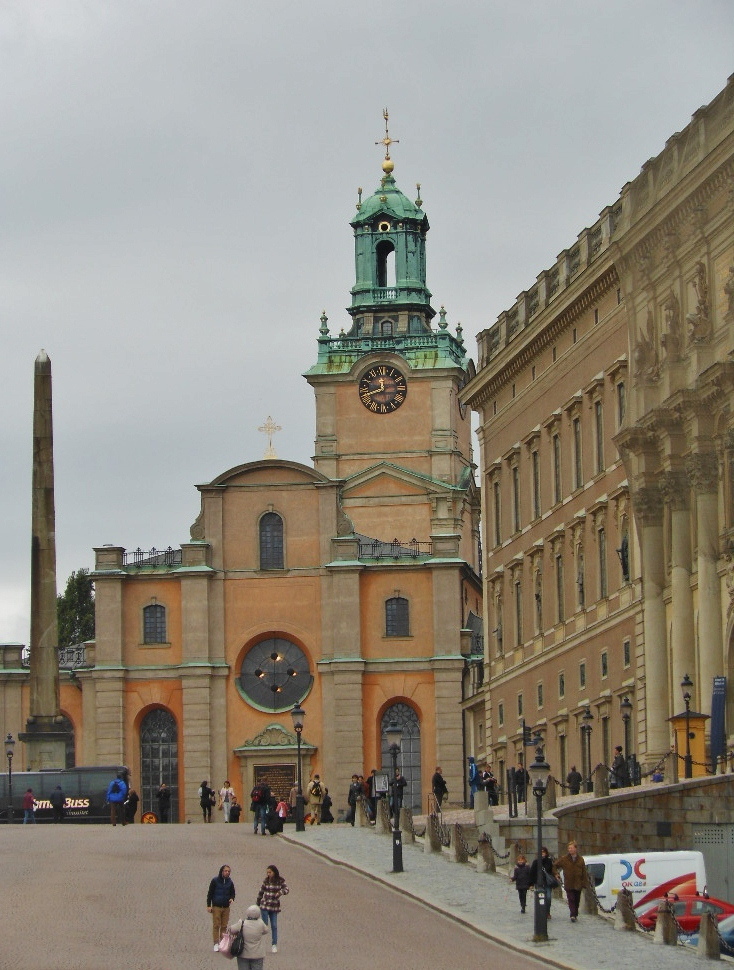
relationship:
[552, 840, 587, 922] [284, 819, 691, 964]
person walking on sidewalk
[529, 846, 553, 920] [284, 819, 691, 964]
person walking on sidewalk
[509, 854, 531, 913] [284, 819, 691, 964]
person walking on sidewalk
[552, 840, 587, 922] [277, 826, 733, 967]
person walking on sidewalk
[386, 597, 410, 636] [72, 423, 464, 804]
window on building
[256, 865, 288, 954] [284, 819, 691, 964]
person walking on sidewalk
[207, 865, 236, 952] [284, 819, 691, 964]
person walking on sidewalk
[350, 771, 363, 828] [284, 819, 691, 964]
person walking on sidewalk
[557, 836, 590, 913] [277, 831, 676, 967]
person walking on sidewalk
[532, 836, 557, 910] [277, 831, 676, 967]
person walking on sidewalk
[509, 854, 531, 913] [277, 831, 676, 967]
person walking on sidewalk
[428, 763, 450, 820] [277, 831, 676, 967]
person walking on sidewalk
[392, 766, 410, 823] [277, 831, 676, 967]
person walking on sidewalk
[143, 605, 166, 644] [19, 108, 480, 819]
window on building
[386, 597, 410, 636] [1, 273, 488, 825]
window on building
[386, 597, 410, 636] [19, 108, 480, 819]
window on building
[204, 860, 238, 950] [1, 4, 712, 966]
person walking outdoors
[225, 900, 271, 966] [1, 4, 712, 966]
person walking outdoors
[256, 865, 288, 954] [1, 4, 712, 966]
person walking outdoors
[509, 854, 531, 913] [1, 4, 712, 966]
person walking outdoors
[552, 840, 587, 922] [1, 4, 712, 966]
person walking outdoors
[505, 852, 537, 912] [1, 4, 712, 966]
person walking outdoors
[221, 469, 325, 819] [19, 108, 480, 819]
wall supporting building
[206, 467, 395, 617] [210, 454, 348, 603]
wall of building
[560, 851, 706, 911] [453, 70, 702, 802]
van parked near building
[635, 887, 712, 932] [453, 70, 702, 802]
car parked near building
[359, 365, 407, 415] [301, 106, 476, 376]
clock on top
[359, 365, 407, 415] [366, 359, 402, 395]
clock has hands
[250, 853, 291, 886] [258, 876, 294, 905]
person wearing plaid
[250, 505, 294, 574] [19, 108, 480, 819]
window on front of building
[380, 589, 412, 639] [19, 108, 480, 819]
window on front of building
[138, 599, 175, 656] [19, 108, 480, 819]
window on front of building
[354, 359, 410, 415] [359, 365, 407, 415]
clock has clock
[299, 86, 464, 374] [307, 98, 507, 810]
top of tower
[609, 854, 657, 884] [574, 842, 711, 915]
logo on side of van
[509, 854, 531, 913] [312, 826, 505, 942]
person on sidewalk